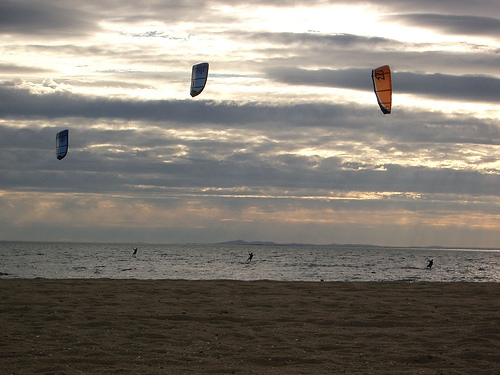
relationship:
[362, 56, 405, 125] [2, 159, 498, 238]
kite in sky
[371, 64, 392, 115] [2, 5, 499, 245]
kite in sky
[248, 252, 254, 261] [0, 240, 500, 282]
figure in ocean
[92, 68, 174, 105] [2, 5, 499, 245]
light in sky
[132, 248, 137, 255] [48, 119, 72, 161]
figure with sail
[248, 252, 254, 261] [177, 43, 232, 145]
figure with sail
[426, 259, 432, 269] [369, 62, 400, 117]
figure with sail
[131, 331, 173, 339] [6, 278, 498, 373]
pit in sand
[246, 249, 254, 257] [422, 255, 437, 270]
arm of person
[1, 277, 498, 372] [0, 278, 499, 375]
footprints in sand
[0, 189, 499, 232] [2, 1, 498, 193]
orange light in clouds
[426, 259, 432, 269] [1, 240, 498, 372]
figure in ocean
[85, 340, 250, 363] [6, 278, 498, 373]
dots over sand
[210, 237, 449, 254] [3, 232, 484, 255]
land seen in distance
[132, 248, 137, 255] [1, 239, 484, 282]
figure kitesurfing in water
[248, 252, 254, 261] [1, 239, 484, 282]
figure kitesurfing in water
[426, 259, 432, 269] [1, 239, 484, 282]
figure kitesurfing in water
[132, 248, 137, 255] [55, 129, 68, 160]
figure controlling kite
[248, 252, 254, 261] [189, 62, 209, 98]
figure controlling kite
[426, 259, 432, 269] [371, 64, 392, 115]
figure controlling kite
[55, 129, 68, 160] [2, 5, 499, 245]
kite flying in sky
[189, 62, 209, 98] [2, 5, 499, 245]
kite flying in sky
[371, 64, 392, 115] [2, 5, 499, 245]
kite flying in sky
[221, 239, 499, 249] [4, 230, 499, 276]
land popping up near horizon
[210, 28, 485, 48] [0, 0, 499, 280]
cloud hanging in sky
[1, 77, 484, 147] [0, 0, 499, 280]
cloud hanging in sky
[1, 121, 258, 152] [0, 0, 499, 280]
cloud hanging in sky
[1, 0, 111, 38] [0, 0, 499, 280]
cloud hanging in sky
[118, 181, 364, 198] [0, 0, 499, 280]
cloud hanging in sky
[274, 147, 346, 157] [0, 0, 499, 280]
sunlight peeking through sky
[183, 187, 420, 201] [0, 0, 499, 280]
sunlight peeking through sky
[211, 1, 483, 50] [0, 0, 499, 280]
sunlight peeking through sky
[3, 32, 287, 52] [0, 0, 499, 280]
sunlight peeking through sky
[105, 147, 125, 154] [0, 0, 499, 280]
sunlight peeking through sky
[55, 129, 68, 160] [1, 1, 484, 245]
kite flying in air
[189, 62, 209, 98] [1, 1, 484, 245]
kite flying in air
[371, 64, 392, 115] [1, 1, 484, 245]
kite flying in air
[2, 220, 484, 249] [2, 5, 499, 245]
streak appearing in sky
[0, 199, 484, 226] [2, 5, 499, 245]
streak appearing in sky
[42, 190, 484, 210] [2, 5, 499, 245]
streak appearing in sky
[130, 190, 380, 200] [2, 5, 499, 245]
streak appearing in sky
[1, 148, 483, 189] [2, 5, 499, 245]
streak appearing in sky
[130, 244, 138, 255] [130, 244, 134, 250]
figure lifting arm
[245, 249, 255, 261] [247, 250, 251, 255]
figure lifting arm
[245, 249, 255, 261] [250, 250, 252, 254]
figure lifting arm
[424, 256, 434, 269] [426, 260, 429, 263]
figure lifting arm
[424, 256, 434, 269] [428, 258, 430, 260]
figure lifting arm